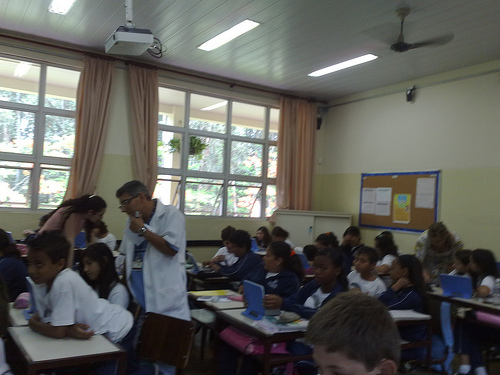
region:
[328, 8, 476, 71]
fan hanging from ceiling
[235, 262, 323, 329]
laptop open on desktop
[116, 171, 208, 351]
man in white coat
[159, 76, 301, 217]
open windows on the bottom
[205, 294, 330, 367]
white desk top with black frame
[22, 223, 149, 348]
boy leaning on desktop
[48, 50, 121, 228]
beige drape at window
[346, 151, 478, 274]
bulletin board hanging on wall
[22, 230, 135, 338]
boy wearing white shirt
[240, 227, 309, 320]
girl with red in hair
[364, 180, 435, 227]
the papers on bulletin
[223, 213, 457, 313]
the children are seated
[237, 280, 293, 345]
computer on the table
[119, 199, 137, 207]
the glasses are black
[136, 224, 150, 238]
the watch is silver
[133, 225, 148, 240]
watch is on wrist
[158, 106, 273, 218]
the plant outside window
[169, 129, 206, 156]
the plant is green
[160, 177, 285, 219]
the windows are open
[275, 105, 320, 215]
the curtains are pink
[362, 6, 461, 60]
Fan hung from the ceiling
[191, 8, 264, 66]
Light built into ceiling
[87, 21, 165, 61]
Projector hanging from the ceiling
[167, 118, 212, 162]
Hanging plant outside window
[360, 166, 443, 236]
Bulletin board on the wall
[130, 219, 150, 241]
Wristwatch worn by teacher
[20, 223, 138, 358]
Student leaning on desk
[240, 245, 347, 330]
Student using a computer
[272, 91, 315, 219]
Pink drapes on the window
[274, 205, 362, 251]
Cabinet in corner of the room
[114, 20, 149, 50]
projector hanging from the ceiling.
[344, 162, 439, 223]
bulletin board on the wall.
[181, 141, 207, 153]
plant hanging outside the window.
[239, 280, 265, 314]
screen on the desk.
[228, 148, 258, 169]
window pane in the classroom.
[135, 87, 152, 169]
curtain on the wall.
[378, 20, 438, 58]
ceiling fan hanging down.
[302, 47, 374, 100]
fluorescent light on the ceiling.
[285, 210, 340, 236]
cabinet in the corner.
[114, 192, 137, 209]
glasses on the man's face.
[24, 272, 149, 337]
White shirt on a boy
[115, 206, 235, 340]
White jacket on a man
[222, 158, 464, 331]
Kids in a class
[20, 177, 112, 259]
Pink shirt on a woman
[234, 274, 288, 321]
Computer on a desk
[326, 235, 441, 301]
Boys and girls at desks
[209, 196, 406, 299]
Children with brown hair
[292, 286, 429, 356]
Child with blonde hair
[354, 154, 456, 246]
Bullitin board on a wall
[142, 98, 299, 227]
Windows in a classroom